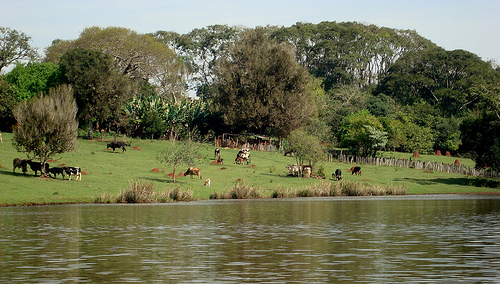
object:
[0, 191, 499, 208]
shoreline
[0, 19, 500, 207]
country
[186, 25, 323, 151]
trees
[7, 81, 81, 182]
tree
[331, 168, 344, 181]
cows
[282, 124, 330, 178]
trees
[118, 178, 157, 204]
grass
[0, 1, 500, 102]
sky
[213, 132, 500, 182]
fence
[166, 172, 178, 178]
piles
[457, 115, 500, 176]
tree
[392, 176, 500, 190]
shadow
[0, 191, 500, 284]
pond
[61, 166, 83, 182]
cow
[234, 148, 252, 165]
cow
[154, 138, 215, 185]
tree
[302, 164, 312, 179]
cow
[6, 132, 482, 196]
field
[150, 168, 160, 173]
piles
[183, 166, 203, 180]
cow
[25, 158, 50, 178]
cow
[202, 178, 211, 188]
calf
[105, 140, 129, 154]
cow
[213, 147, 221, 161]
cow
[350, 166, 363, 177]
cow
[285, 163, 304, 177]
cow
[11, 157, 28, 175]
cow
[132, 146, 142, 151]
haystacks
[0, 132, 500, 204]
grass